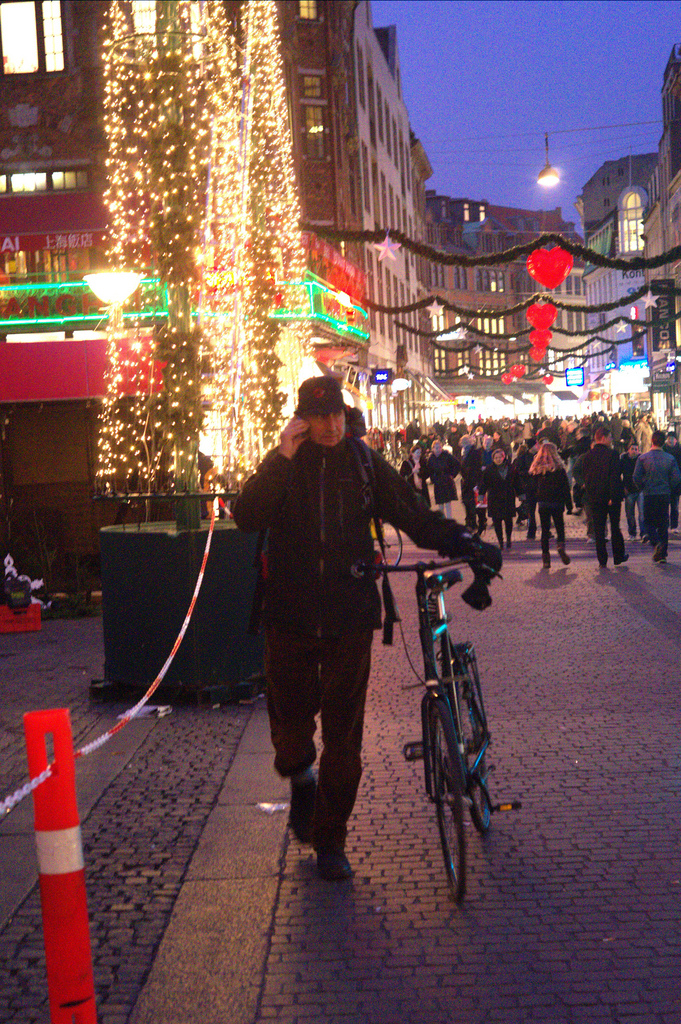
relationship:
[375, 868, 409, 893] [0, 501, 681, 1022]
brick in a ground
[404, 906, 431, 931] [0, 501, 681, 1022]
brick in a ground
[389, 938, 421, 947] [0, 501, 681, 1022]
brick in a ground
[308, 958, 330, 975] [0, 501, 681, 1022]
brick in a ground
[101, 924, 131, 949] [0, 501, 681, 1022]
brick in a ground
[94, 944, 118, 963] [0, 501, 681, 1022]
brick in a ground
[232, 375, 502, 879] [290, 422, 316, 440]
man talking on cellphone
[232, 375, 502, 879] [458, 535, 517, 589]
man wearing glove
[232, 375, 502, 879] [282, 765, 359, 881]
man wearing shoes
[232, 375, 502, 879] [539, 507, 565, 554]
man wearing jeans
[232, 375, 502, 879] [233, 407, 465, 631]
man wearing jacket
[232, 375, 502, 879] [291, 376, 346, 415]
man wearing hat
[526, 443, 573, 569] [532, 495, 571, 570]
person wearing jeans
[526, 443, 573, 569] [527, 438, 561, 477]
person has hair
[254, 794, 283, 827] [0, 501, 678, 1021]
wrapper on ground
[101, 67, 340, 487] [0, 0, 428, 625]
lights are hanging from building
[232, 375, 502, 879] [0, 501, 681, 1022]
man walking on ground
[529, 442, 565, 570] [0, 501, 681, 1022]
person walking on ground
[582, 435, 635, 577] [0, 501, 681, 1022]
person walking on ground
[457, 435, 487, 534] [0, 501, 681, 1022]
person walking on ground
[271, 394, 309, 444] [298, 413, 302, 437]
man has cellphone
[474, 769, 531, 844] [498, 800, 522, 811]
pedal has pedal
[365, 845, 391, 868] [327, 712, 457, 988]
brick in a sidewalk